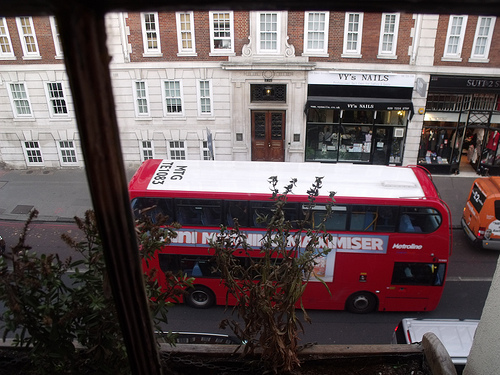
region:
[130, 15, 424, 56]
the windows are closed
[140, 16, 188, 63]
window pane is white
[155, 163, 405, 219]
bus' roof is white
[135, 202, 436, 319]
the bus is red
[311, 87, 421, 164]
the store front is black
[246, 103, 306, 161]
the door is closed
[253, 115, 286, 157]
the door is brown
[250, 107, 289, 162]
the door frame is made of wood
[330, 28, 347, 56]
the wall is red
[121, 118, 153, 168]
the wall is white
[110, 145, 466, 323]
Red and white bus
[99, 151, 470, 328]
Red and white double decker bus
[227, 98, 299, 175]
Brown door with glass windows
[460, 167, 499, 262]
Orange and white automobile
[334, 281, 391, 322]
Rubber bus tire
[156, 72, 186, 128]
Glass window with white trim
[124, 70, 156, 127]
Glass window with white trim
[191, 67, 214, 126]
Glass window with white trim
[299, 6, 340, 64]
Glass window with white trim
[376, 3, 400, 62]
Glass window with white trim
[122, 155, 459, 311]
A bus is parked on the street.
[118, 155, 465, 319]
The bus is red.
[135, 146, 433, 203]
The bus has a white roof.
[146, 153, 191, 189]
Letters and numbers are printed on the roof.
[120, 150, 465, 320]
The bus is a double decker.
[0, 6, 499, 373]
The scene is outside a window.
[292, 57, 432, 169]
A nail salon is across the street.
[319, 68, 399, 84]
The salon's name is VY's nails.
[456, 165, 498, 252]
An orange vehicle is in front of the bus.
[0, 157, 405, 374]
Plants are on the windowsill.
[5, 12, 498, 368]
street photographed from above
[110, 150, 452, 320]
red and white two-story bus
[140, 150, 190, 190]
black text on top of bus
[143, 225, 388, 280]
sign on the side of the bus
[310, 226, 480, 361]
white vehicle beside bus on the road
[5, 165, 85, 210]
sidewalk appears grey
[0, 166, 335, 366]
dry-looking plants in foreground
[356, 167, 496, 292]
orange vehicle in front of bus on the road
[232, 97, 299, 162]
wooden double doors of building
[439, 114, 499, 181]
open entrance of shop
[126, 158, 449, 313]
a red bus with a white top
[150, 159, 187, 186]
MTG TE1083 is in black on the white top of a red bus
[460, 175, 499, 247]
the back of an orange vehicle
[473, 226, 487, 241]
illuminated red brake light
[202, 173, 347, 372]
a dying plant outside a window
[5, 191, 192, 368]
two plants outside a window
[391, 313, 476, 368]
a silver vehicle on the road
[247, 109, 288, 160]
dark brown doors on a white building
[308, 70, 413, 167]
a black shop with VY'S NAILS above it over white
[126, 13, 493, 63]
many white windows on a brick building